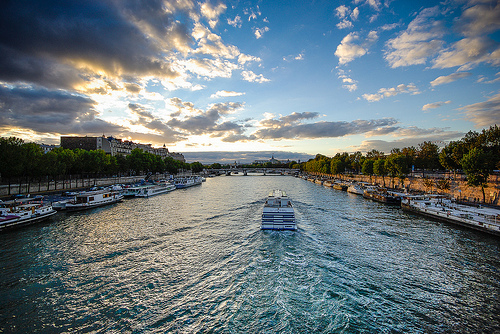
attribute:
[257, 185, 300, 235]
ship — white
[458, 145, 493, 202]
tree — green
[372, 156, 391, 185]
tree — green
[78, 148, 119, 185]
tree — green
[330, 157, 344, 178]
tree — green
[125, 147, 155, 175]
tree — green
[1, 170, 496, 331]
water — blue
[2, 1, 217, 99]
cloud — large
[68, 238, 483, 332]
water — calm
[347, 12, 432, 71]
clouds — white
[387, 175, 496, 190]
ground — sand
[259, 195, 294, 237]
boat — big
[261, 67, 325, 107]
sky — blue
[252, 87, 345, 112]
sky — blue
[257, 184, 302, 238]
boat — traveling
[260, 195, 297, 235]
boat — white